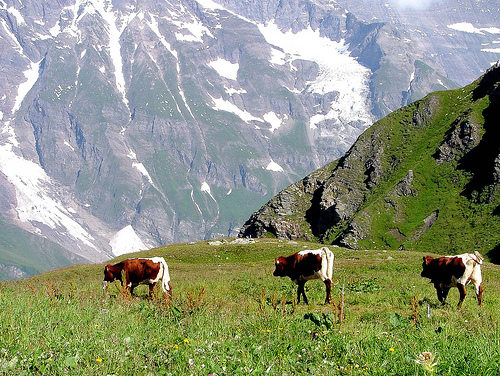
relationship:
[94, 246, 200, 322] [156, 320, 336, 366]
cow grazing grass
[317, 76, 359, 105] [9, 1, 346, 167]
snow on mountain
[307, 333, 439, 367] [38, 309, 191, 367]
flowers in grass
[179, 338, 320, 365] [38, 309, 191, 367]
weeds in grass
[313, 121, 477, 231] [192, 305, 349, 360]
hill with grass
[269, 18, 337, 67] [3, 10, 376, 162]
snow with mountain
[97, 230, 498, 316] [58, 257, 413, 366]
cows in grass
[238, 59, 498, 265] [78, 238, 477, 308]
hill by cows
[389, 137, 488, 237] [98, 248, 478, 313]
greenery by cows